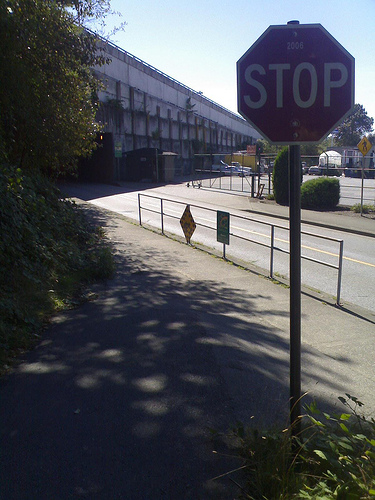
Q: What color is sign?
A: Red and white.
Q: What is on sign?
A: STOP.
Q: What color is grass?
A: Green.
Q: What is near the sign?
A: Grey concrete path.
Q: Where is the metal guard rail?
A: On the street.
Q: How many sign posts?
A: Two.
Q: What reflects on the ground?
A: Shadow of the trees.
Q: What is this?
A: Part of a walking path.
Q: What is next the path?
A: Part of a bushy bush.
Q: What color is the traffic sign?
A: Red.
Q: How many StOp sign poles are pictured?
A: One.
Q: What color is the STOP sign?
A: Red and white.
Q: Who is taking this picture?
A: Traveler.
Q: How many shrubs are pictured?
A: Two.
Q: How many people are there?
A: None.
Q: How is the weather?
A: Sunny.